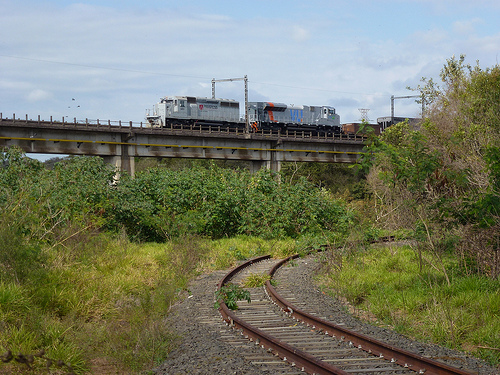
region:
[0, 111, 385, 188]
train on bridge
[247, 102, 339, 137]
silver train engine with red stripe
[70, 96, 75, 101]
birds flying above bridge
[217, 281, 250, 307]
weeds growing in railroad tracks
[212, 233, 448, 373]
rusty curved railroad tracks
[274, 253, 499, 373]
gravel next to railroad tracks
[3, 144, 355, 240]
bushes under train bridge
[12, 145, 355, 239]
bushes are green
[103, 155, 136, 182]
concrete bridge supports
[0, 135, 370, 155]
yellow line across train bridge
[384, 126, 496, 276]
The trees are leafy.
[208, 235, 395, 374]
The track is clear.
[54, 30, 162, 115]
The sky is clear.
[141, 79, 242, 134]
The train is white.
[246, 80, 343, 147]
The train is grey.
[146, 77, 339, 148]
The trains are on the track.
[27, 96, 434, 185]
The track is elevated.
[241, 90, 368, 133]
The train has red and blue on it.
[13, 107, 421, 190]
The track is brown.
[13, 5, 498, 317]
It is a nice and clear day.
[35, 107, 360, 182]
Train tracks across a bridge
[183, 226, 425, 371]
Train tracks around a curve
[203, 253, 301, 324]
Weeds growing on the train tracks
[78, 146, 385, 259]
Bushes growing beside train tracks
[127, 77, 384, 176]
A train going across a bridge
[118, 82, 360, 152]
Two train engines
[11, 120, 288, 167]
Rusted metal bridge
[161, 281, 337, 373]
Gravel under train tracks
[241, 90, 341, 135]
Red striped train engine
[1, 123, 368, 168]
Yellow pipe running along the side of a bridge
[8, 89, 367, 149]
two trains riding across a railroad bridge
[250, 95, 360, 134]
a red and blue train crossing a bridge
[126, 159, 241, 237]
a green tree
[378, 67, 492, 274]
a half dead tree across from railroad tracks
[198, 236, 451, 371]
a curve in the railroad track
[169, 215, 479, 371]
weeds growing on railroad track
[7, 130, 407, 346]
many shrubs and weeds growing by railroad track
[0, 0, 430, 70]
cloudy day with blue skies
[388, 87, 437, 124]
two poles that determine height that can go under them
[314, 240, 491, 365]
a grass and gravel patch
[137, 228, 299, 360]
the railroad is rusty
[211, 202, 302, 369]
the railroad is rusty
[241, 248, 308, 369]
the railroad is rusty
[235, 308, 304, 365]
the railroad is rusty